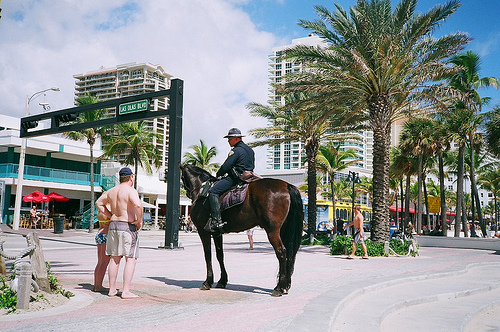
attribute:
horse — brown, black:
[199, 182, 311, 295]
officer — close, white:
[217, 123, 270, 179]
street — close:
[313, 243, 488, 332]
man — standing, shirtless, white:
[104, 169, 150, 296]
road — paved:
[36, 226, 76, 255]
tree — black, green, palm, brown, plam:
[303, 16, 479, 231]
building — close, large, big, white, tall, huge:
[83, 66, 172, 164]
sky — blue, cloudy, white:
[105, 2, 259, 67]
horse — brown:
[171, 168, 308, 290]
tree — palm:
[312, 4, 430, 253]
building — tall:
[257, 23, 363, 173]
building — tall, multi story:
[269, 32, 382, 180]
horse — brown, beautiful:
[179, 165, 320, 287]